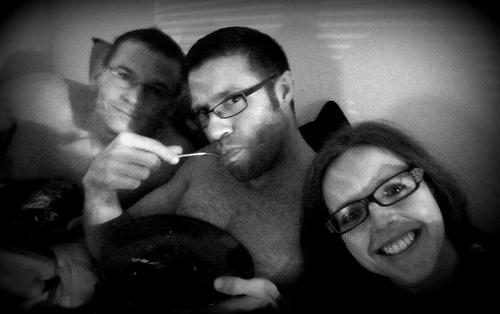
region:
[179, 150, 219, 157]
Silverware in the man's mouth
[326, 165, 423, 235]
The woman is wearing glasses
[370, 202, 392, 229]
The nose of the woman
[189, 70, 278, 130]
The man has glasses on his face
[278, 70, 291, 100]
The left ear of the man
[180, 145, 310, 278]
The man is not wearing a shirt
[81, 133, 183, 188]
The right hand of the man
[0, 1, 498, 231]
A wall behind the people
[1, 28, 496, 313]
Three people by a wall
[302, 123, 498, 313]
A woman next to two men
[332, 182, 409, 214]
the lady is wearing glasses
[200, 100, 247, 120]
he is wearing glasses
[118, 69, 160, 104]
the guy is wearing glasses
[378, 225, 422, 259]
the lady is smiling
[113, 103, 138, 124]
the guy is smiling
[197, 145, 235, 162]
he has a utencil in his mouth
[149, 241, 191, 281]
the plate is empty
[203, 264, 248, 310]
he is holding the plate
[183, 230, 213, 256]
the plate is black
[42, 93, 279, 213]
they are both shirtless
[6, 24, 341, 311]
the men are topless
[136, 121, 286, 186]
a fork in his mouth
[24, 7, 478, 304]
all three of them are wearing glasses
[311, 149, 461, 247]
her glasses are black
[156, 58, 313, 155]
his glasses frame is black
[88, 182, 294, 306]
a dark colored plate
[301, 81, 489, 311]
she is showing her teeth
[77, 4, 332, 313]
he is not wearing a shirt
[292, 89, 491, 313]
she has dark hair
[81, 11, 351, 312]
he is eating in bed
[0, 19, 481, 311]
Three people in the forefront.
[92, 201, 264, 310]
Plate in the hand.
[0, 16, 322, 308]
Two men in bed.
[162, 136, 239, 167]
Metal eating utensil in mouth.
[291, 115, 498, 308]
Woman in the forefront.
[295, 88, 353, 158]
Pillow behind the man.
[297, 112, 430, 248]
Glasses on the woman.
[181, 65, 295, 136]
Glasses on the man.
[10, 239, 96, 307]
Blanket on the bed.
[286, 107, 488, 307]
Long hair on the woman.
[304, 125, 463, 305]
this is a person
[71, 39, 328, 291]
this is a person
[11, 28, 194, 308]
this is a person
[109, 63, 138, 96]
the eye of a person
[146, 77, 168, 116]
the eye of a person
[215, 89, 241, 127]
the eye of a person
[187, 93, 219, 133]
the eye of a person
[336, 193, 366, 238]
the eye of a person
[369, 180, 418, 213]
the eye of a person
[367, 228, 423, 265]
the smiling mouth of a lady